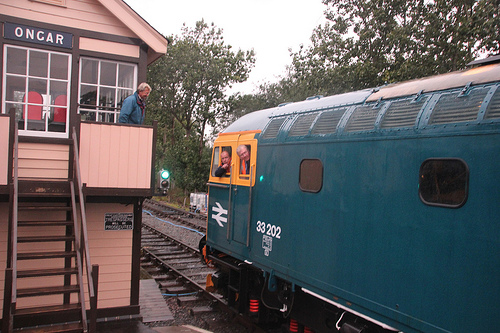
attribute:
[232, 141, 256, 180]
person — ooking out, open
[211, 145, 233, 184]
person — looking out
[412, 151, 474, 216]
window — closed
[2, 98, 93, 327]
entrance — wooden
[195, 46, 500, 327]
train — yellow, teal, blue, orange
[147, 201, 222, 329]
rail — big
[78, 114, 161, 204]
balcony — tan, brown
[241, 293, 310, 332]
springs — orange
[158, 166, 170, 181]
green light — lit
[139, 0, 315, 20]
sky — cloudy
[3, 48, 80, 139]
window — large